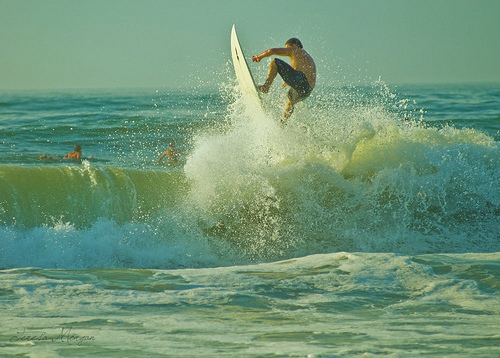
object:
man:
[253, 37, 316, 127]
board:
[230, 24, 260, 97]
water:
[151, 111, 297, 258]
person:
[40, 143, 81, 161]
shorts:
[275, 54, 313, 102]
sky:
[56, 11, 159, 64]